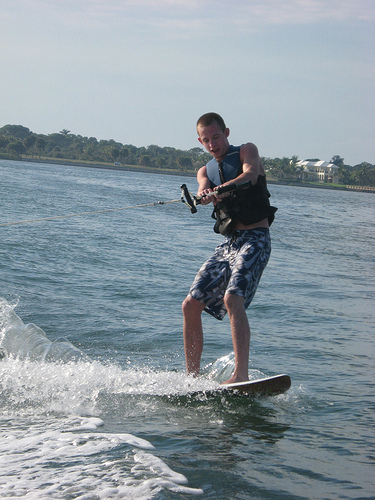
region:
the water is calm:
[65, 225, 157, 305]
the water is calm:
[297, 273, 368, 396]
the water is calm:
[78, 236, 232, 312]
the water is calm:
[298, 271, 346, 352]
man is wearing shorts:
[178, 212, 272, 324]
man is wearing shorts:
[173, 199, 279, 335]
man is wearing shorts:
[185, 215, 268, 321]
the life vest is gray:
[187, 146, 285, 259]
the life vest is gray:
[169, 150, 268, 243]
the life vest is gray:
[160, 151, 272, 224]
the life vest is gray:
[191, 137, 276, 254]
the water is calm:
[41, 234, 143, 299]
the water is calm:
[275, 236, 358, 366]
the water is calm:
[265, 261, 364, 398]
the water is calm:
[280, 215, 373, 397]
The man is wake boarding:
[142, 105, 293, 402]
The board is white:
[145, 366, 291, 410]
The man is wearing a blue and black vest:
[201, 143, 277, 236]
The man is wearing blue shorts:
[184, 226, 271, 318]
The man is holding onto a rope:
[132, 101, 299, 399]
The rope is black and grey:
[6, 182, 198, 259]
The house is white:
[292, 154, 341, 188]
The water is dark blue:
[2, 152, 371, 496]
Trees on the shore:
[0, 122, 372, 193]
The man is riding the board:
[156, 106, 292, 405]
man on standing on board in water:
[39, 93, 343, 456]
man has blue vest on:
[180, 154, 286, 237]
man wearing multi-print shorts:
[173, 217, 288, 331]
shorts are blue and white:
[184, 225, 280, 321]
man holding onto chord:
[12, 93, 279, 224]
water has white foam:
[30, 392, 198, 499]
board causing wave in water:
[2, 306, 304, 449]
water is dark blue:
[33, 164, 164, 320]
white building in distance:
[274, 135, 357, 202]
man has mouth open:
[199, 137, 226, 157]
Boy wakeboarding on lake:
[93, 103, 319, 429]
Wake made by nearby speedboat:
[9, 308, 371, 494]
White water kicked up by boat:
[1, 332, 120, 498]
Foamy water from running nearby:
[2, 345, 164, 498]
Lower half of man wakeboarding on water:
[131, 217, 313, 427]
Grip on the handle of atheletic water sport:
[142, 175, 241, 223]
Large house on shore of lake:
[278, 149, 356, 196]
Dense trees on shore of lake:
[5, 130, 190, 188]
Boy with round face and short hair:
[185, 109, 253, 163]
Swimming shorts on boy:
[169, 232, 289, 325]